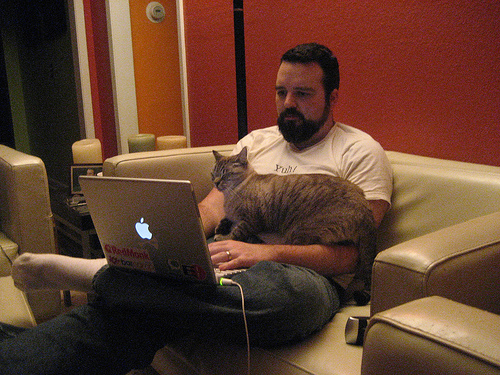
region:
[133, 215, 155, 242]
glowing computer logo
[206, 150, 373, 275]
a house cat is sitting on the man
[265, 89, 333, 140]
the man has a beard and mustache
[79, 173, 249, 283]
a laptop on the man's legs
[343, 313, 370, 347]
a remote control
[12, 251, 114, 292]
white sock on the man's foot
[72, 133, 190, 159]
decorative candles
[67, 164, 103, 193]
a small framed picture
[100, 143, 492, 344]
a white leather chair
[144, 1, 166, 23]
temperature control panel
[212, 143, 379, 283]
Cat on a man's lap.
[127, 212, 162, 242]
Apple on the back of a computer.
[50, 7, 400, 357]
Man playing on a laptop.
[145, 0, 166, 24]
Alarm on the wall.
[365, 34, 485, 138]
A wall painted in red.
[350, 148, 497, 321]
A beige leather chair.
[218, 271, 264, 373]
Cord to a computer.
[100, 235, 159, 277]
Sticker on the back of a computer.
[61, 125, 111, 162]
Candle on the table.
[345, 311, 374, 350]
Television remote in the chair.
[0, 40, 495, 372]
A man sitting on a couch with a computer.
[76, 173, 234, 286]
An Apple MacBook Pro.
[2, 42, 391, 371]
A man with a cat lying on him.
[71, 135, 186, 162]
Three large candles that are different colors.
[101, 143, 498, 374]
A beige leather couch.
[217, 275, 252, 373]
The power cord for the laptop.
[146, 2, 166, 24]
A smoke detector on the wall.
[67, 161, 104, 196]
A framed photo on the table.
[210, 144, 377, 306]
The cat has its eyes closed.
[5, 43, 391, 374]
The man is wearing jeans and a t-shirt.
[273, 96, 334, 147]
Facial hair on man's face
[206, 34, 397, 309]
A cat sitting on a man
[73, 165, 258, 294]
An Apple laptop computer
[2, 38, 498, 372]
The man is sitting on a couch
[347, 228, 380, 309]
The tail of a cat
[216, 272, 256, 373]
A white electrical wire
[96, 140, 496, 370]
A beige leather couch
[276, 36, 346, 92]
Brown hair on man's head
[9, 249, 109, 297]
A sock is white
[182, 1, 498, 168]
Red wall behind the couch